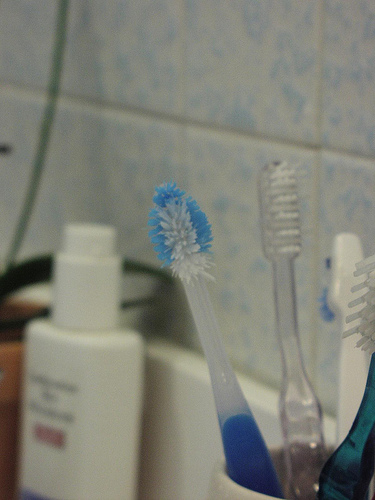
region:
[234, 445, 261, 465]
part of a bruash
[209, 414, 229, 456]
edge of a brush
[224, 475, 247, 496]
edge of a cup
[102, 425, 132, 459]
part of a handle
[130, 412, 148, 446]
edge of a board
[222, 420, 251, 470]
part of a bruash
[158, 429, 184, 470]
part of a wall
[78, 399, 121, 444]
part of a board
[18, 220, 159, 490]
White bottle of lotion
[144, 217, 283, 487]
Blue and white tooth brush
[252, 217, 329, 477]
The toothbrush is clear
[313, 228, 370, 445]
White toothbrush with blue bristles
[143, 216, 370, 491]
The tooth brushes are in a white cup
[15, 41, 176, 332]
Green plant next to the wall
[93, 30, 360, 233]
White tiles with blue speckles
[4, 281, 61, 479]
The pot is brown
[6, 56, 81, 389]
The plant is in a pot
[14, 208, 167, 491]
The lotion is next to the pot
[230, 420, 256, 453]
part of a brush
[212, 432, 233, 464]
edge of a brush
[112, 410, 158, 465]
edge of a bottle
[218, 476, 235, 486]
edge of a cup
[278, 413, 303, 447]
part of a brush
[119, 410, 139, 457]
edge of a bottle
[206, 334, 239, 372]
part of a brush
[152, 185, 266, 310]
old blue toothbrush bristles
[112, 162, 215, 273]
old blue toothbrush bristles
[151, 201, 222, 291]
old blue toothbrush bristles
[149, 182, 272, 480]
a blue and clear toothbrush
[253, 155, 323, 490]
a clear and white toothbrush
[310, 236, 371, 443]
a white and blue toothbrush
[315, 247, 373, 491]
a transparent blue and white toothbrush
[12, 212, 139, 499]
a white spray bottle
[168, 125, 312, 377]
a blue speckled white tile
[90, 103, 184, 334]
a blue speckled white tile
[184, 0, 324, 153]
a blue speckled white tile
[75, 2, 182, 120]
a blue speckled white tile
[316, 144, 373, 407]
a blue speckled white tile